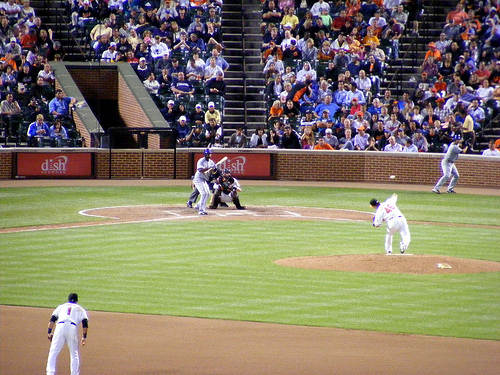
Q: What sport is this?
A: Baseball.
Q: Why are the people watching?
A: Entertainment.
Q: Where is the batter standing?
A: On the mound.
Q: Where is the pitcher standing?
A: ON the pitching mound.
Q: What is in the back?
A: The audience.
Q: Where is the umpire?
A: Behind the catcher.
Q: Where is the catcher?
A: Behind the batter.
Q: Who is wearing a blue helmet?
A: The batter.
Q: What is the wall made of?
A: Bricks.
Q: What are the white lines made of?
A: Chalk.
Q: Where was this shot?
A: Outfield.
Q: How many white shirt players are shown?
A: 3.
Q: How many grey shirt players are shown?
A: 2.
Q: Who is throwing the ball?
A: Pitcher.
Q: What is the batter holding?
A: Baseball bat.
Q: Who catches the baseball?
A: Catcher.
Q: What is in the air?
A: Baseball.